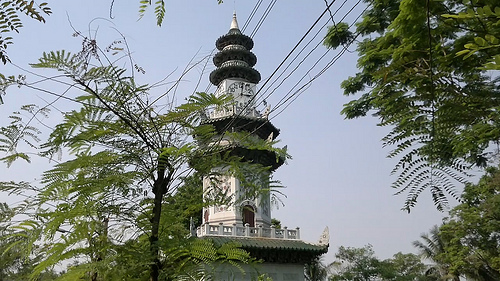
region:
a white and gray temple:
[186, 79, 296, 252]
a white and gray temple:
[179, 38, 251, 273]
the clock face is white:
[205, 67, 274, 126]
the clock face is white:
[193, 60, 295, 140]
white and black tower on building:
[180, 13, 298, 237]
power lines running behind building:
[128, 1, 398, 223]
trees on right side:
[321, 8, 486, 279]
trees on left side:
[8, 8, 207, 279]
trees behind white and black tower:
[14, 235, 474, 279]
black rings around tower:
[179, 33, 286, 162]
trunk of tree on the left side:
[143, 144, 171, 275]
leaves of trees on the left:
[2, 2, 223, 279]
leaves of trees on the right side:
[320, 5, 498, 280]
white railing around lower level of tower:
[187, 219, 307, 236]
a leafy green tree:
[4, 56, 276, 278]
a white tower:
[178, 11, 330, 278]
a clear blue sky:
[293, 148, 398, 227]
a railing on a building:
[202, 225, 309, 238]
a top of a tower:
[212, 11, 254, 86]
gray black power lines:
[280, 24, 336, 113]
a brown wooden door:
[239, 202, 256, 234]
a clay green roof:
[205, 238, 324, 256]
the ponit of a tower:
[224, 13, 239, 35]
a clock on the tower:
[227, 79, 257, 110]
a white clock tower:
[192, 8, 305, 244]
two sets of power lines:
[130, 5, 360, 195]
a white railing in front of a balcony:
[175, 211, 300, 236]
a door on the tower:
[230, 197, 260, 229]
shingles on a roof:
[185, 225, 325, 250]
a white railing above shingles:
[176, 208, 317, 258]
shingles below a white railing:
[161, 218, 321, 259]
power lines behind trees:
[2, 50, 202, 128]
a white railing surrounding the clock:
[187, 78, 273, 126]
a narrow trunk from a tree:
[124, 149, 176, 279]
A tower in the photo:
[183, 10, 306, 240]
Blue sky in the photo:
[322, 117, 377, 218]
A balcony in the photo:
[208, 224, 299, 241]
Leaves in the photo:
[75, 87, 135, 230]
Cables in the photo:
[248, 0, 310, 37]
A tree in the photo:
[144, 137, 189, 245]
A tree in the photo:
[138, 157, 175, 276]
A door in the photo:
[241, 201, 258, 236]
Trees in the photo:
[397, 190, 497, 272]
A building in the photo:
[215, 116, 280, 280]